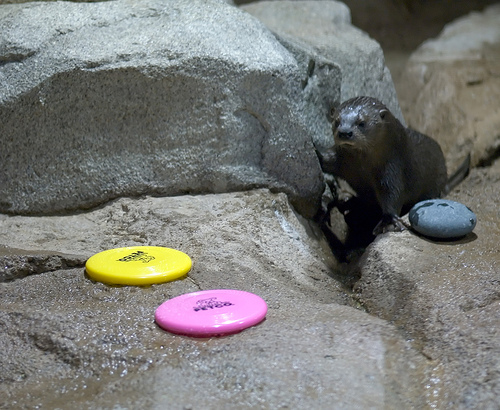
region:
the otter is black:
[313, 90, 497, 206]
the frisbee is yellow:
[68, 239, 208, 286]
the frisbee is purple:
[150, 284, 273, 339]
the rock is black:
[408, 188, 478, 238]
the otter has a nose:
[334, 120, 359, 142]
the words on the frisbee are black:
[191, 292, 233, 317]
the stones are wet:
[63, 310, 151, 388]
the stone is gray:
[16, 4, 293, 189]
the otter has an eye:
[346, 110, 375, 133]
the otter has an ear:
[373, 112, 390, 120]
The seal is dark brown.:
[320, 90, 465, 235]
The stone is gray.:
[406, 196, 476, 238]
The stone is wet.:
[407, 196, 472, 236]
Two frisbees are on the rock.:
[81, 221, 267, 336]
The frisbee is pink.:
[151, 286, 271, 336]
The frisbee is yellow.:
[80, 240, 190, 281]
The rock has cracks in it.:
[4, 165, 499, 405]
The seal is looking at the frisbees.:
[75, 85, 472, 340]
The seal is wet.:
[311, 95, 478, 237]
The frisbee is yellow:
[83, 244, 192, 286]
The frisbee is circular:
[153, 290, 268, 335]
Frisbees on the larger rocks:
[86, 246, 266, 335]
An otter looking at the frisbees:
[318, 97, 446, 232]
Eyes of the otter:
[333, 115, 366, 129]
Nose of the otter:
[341, 127, 351, 139]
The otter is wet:
[317, 96, 447, 231]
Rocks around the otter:
[0, 1, 496, 406]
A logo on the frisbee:
[193, 297, 235, 315]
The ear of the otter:
[376, 107, 393, 122]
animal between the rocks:
[298, 58, 467, 230]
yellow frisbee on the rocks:
[56, 225, 206, 290]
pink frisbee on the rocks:
[157, 285, 280, 337]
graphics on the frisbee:
[190, 295, 235, 317]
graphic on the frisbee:
[120, 248, 160, 266]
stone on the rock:
[395, 193, 477, 239]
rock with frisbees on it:
[5, 204, 400, 369]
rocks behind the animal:
[290, 7, 482, 79]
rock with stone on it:
[378, 201, 489, 328]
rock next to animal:
[14, 11, 319, 190]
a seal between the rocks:
[317, 91, 468, 268]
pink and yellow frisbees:
[70, 231, 270, 346]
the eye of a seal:
[356, 115, 368, 133]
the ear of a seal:
[374, 107, 388, 125]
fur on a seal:
[346, 95, 378, 111]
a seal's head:
[331, 105, 391, 147]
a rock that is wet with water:
[15, 311, 155, 406]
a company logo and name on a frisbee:
[190, 290, 238, 313]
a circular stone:
[411, 197, 478, 246]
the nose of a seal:
[337, 129, 356, 141]